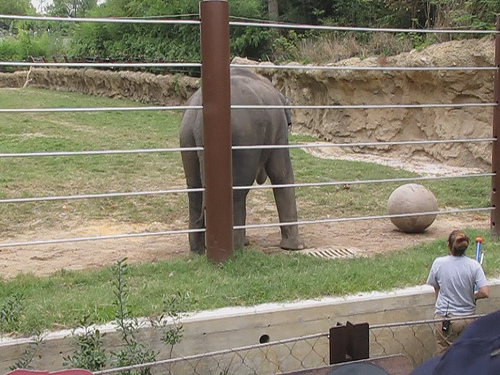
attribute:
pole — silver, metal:
[10, 102, 201, 122]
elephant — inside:
[172, 64, 305, 250]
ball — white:
[375, 167, 458, 247]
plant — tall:
[53, 247, 198, 374]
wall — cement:
[28, 265, 489, 362]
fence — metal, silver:
[6, 148, 219, 160]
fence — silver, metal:
[241, 202, 493, 234]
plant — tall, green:
[65, 249, 185, 374]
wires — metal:
[230, 19, 500, 39]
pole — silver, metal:
[0, 177, 202, 217]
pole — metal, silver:
[229, 137, 498, 149]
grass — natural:
[192, 265, 316, 290]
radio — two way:
[439, 299, 451, 335]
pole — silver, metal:
[234, 97, 491, 117]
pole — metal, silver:
[3, 58, 203, 72]